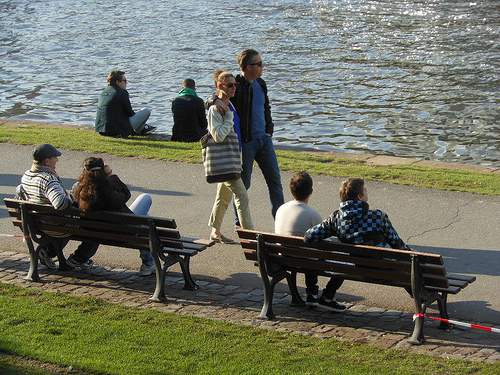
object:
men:
[303, 177, 413, 308]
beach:
[394, 173, 500, 340]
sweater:
[303, 200, 412, 265]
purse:
[200, 102, 242, 184]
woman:
[201, 69, 256, 245]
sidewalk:
[0, 141, 500, 332]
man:
[233, 49, 286, 231]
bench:
[3, 197, 218, 302]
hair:
[71, 169, 111, 212]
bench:
[237, 227, 478, 345]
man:
[171, 78, 209, 143]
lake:
[1, 0, 500, 164]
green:
[178, 88, 198, 97]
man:
[95, 68, 151, 137]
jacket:
[95, 86, 136, 135]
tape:
[413, 313, 500, 335]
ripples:
[27, 13, 499, 124]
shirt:
[251, 80, 266, 139]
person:
[16, 144, 100, 270]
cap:
[33, 143, 62, 161]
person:
[273, 171, 347, 313]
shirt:
[275, 200, 332, 268]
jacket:
[21, 164, 81, 238]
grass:
[416, 165, 500, 196]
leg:
[257, 273, 279, 321]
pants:
[208, 178, 254, 232]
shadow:
[0, 172, 193, 195]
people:
[70, 156, 170, 276]